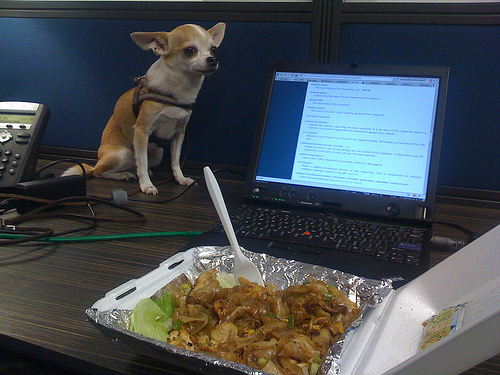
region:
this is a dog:
[92, 32, 237, 195]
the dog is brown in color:
[111, 101, 135, 131]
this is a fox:
[198, 163, 243, 231]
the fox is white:
[199, 170, 226, 204]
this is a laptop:
[266, 101, 433, 245]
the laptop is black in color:
[366, 200, 411, 220]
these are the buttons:
[273, 211, 328, 233]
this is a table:
[18, 255, 77, 355]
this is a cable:
[29, 194, 69, 241]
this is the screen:
[284, 80, 391, 175]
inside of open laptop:
[194, 63, 448, 280]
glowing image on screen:
[254, 70, 438, 197]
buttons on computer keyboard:
[238, 212, 418, 266]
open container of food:
[85, 225, 497, 373]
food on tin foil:
[104, 262, 361, 362]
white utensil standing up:
[202, 165, 266, 292]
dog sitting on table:
[65, 19, 228, 191]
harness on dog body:
[130, 82, 195, 148]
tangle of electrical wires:
[0, 192, 195, 254]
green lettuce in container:
[131, 294, 177, 341]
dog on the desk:
[86, 14, 235, 184]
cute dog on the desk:
[112, 12, 230, 205]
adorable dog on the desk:
[92, 17, 232, 187]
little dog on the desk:
[112, 8, 228, 205]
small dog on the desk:
[105, 16, 228, 196]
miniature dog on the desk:
[92, 18, 227, 192]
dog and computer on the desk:
[84, 0, 454, 268]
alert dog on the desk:
[112, 10, 232, 192]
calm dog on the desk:
[74, 9, 267, 187]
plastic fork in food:
[176, 161, 286, 319]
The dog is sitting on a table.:
[47, 2, 240, 200]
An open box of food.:
[46, 235, 496, 371]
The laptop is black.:
[188, 54, 453, 277]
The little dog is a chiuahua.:
[55, 10, 231, 200]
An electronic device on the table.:
[0, 96, 52, 198]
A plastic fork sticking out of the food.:
[201, 160, 259, 305]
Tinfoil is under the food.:
[91, 241, 391, 372]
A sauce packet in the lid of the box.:
[413, 297, 469, 355]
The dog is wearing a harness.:
[126, 77, 197, 152]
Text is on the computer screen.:
[292, 81, 427, 197]